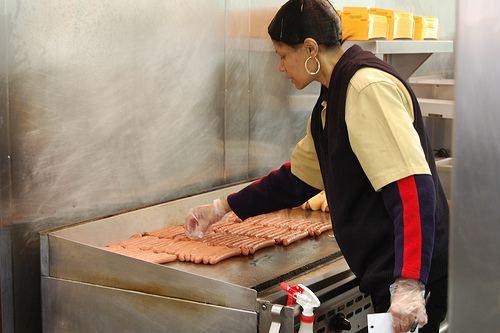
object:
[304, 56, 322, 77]
earrings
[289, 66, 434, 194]
t-shirt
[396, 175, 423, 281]
red stripe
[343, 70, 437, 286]
sleeve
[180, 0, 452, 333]
person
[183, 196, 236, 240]
gloves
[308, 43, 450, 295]
vest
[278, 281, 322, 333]
spray bottle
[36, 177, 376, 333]
grill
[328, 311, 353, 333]
knob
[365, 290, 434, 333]
paper and pen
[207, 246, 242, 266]
hotdogs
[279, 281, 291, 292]
nozzle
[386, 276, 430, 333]
glove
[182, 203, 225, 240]
right hand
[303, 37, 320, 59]
ear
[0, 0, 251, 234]
wall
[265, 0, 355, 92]
head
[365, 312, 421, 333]
paper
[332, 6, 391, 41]
containers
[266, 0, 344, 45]
hairnet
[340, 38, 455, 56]
shelf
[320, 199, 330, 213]
buns